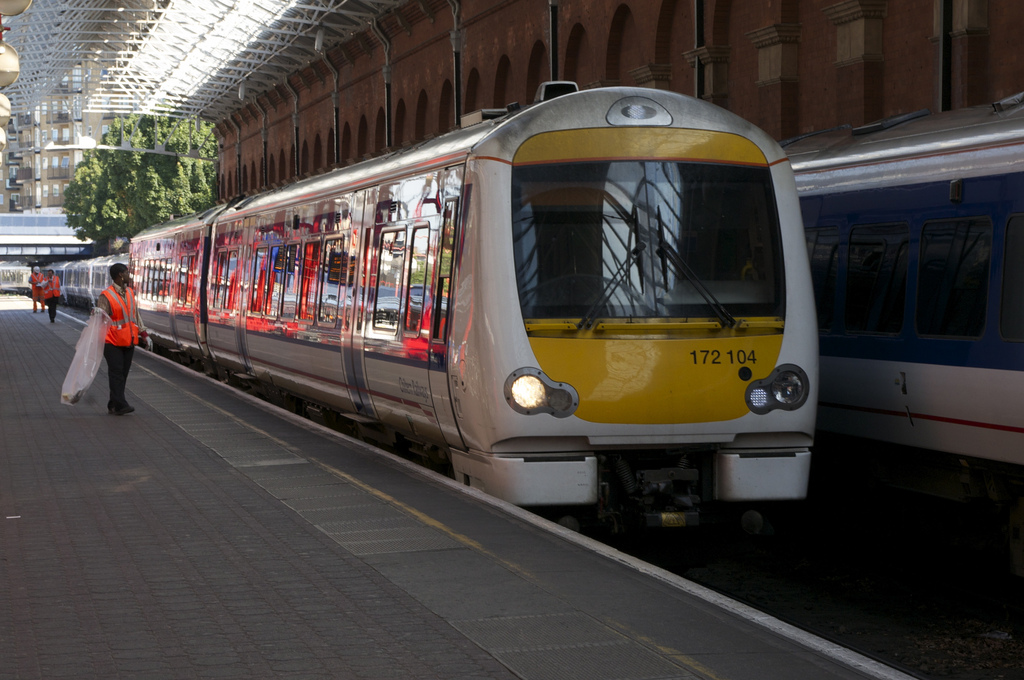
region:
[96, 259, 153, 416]
man in an orange vest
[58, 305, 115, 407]
plastic bag a man is holding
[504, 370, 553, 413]
headlight of a train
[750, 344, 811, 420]
headlight of a train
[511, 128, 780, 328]
front windshield of a train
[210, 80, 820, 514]
first car of a train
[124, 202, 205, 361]
second car of a train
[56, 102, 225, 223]
tree behind a train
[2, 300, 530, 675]
brick walkway near a train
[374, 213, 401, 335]
window on a parked train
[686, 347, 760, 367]
the numbers are in black print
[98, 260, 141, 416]
the person is standing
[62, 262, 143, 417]
the person standing is holding a bag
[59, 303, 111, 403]
the plastic bag is white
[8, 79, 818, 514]
the train is very long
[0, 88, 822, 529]
the yellow paint on the the front of the train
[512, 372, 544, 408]
the light is turned on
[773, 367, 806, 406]
the light is turned off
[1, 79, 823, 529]
the people next to the train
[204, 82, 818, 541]
a commuter train engine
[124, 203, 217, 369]
a train passenger car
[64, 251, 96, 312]
a train passenger car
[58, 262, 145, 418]
a worker picking up trash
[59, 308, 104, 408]
a large trash pad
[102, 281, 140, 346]
a bright orange safety vest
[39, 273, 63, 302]
a bright orange safety vest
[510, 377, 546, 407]
a lit train headlight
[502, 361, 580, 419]
headlight of a commuter train in the station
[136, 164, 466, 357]
reflection on the side of the train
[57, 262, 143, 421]
person in a safety vest standing on the station platform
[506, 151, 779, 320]
front windshield of the yellow commuter train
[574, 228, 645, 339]
windshield wiper on the windshield of the train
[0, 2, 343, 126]
exposed ceiling scaffolding and skylight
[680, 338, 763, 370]
trains identification numbers displayed on the train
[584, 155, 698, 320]
reflection of the skylight on the windshield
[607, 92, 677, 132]
center headlight of the commuter train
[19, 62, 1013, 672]
the train is at the platform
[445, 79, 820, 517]
the front of the train is white and yellow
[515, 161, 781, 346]
the window of the train has windshield wipers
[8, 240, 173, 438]
the workers are wearing orange vests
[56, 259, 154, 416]
the worker is carrying a large plastic bag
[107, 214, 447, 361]
windows are along the side of the train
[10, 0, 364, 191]
a roof is over the station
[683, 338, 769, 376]
a number is on the front of the train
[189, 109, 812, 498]
silver and yellow passenger train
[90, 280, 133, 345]
orange safety vest worn by person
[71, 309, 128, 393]
white trash bag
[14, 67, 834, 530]
long train with yellow face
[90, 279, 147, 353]
orange vest on person standing on platform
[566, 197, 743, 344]
windshield wipers on windshield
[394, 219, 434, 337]
window on side of train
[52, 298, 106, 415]
plastic bag in hand of person in orange vest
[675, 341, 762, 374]
numbers in black on front of train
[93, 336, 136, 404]
pair of black pants on person standing on platform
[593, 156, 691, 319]
white light reflected on windshield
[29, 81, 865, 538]
train on the tracks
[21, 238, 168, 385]
people on the platform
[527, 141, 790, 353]
front window on train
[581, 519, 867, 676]
white trim on platform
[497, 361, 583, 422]
light on the train